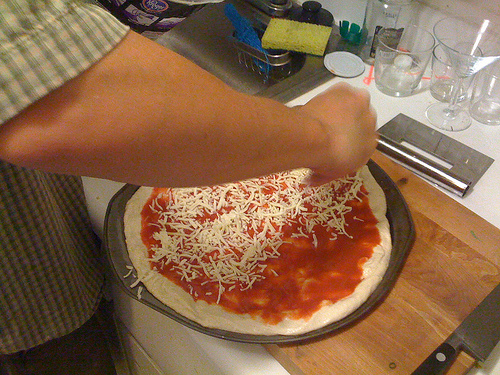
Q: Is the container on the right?
A: Yes, the container is on the right of the image.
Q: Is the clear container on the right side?
A: Yes, the container is on the right of the image.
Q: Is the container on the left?
A: No, the container is on the right of the image.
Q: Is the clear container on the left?
A: No, the container is on the right of the image.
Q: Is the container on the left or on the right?
A: The container is on the right of the image.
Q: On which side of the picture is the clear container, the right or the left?
A: The container is on the right of the image.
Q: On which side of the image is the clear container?
A: The container is on the right of the image.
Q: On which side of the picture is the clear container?
A: The container is on the right of the image.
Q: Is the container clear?
A: Yes, the container is clear.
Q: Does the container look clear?
A: Yes, the container is clear.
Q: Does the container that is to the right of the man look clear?
A: Yes, the container is clear.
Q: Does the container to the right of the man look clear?
A: Yes, the container is clear.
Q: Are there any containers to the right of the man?
A: Yes, there is a container to the right of the man.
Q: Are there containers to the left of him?
A: No, the container is to the right of the man.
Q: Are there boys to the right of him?
A: No, there is a container to the right of the man.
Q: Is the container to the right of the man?
A: Yes, the container is to the right of the man.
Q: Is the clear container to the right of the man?
A: Yes, the container is to the right of the man.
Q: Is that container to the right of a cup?
A: No, the container is to the right of the man.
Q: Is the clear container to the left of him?
A: No, the container is to the right of the man.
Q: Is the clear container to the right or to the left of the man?
A: The container is to the right of the man.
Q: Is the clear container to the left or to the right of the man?
A: The container is to the right of the man.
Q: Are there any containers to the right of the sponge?
A: Yes, there is a container to the right of the sponge.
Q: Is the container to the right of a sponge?
A: Yes, the container is to the right of a sponge.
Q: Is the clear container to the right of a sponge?
A: Yes, the container is to the right of a sponge.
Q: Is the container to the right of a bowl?
A: No, the container is to the right of a sponge.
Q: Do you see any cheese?
A: Yes, there is cheese.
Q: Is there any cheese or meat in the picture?
A: Yes, there is cheese.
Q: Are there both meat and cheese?
A: No, there is cheese but no meat.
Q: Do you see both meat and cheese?
A: No, there is cheese but no meat.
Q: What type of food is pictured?
A: The food is cheese.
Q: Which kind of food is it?
A: The food is cheese.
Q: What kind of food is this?
A: That is cheese.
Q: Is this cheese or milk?
A: This is cheese.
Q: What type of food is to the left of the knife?
A: The food is cheese.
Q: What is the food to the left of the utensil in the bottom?
A: The food is cheese.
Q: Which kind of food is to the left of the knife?
A: The food is cheese.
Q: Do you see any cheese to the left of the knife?
A: Yes, there is cheese to the left of the knife.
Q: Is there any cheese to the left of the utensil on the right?
A: Yes, there is cheese to the left of the knife.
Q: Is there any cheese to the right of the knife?
A: No, the cheese is to the left of the knife.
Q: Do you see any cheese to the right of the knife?
A: No, the cheese is to the left of the knife.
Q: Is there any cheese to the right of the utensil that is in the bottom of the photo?
A: No, the cheese is to the left of the knife.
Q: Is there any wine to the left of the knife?
A: No, there is cheese to the left of the knife.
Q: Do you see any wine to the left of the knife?
A: No, there is cheese to the left of the knife.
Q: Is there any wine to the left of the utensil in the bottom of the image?
A: No, there is cheese to the left of the knife.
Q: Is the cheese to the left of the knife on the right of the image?
A: Yes, the cheese is to the left of the knife.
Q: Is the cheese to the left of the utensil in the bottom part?
A: Yes, the cheese is to the left of the knife.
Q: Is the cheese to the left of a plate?
A: No, the cheese is to the left of the knife.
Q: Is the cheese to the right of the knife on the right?
A: No, the cheese is to the left of the knife.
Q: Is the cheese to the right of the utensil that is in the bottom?
A: No, the cheese is to the left of the knife.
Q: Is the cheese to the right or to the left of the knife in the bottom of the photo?
A: The cheese is to the left of the knife.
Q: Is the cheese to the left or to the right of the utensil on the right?
A: The cheese is to the left of the knife.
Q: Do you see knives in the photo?
A: Yes, there is a knife.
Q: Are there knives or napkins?
A: Yes, there is a knife.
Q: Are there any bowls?
A: No, there are no bowls.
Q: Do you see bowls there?
A: No, there are no bowls.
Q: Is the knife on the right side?
A: Yes, the knife is on the right of the image.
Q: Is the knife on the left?
A: No, the knife is on the right of the image.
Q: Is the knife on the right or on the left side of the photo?
A: The knife is on the right of the image.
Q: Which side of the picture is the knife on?
A: The knife is on the right of the image.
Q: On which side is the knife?
A: The knife is on the right of the image.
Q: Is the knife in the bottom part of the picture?
A: Yes, the knife is in the bottom of the image.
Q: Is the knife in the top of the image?
A: No, the knife is in the bottom of the image.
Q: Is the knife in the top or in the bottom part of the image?
A: The knife is in the bottom of the image.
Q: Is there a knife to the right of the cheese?
A: Yes, there is a knife to the right of the cheese.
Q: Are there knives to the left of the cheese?
A: No, the knife is to the right of the cheese.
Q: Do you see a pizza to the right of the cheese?
A: No, there is a knife to the right of the cheese.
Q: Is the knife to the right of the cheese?
A: Yes, the knife is to the right of the cheese.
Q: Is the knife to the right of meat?
A: No, the knife is to the right of the cheese.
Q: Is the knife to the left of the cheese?
A: No, the knife is to the right of the cheese.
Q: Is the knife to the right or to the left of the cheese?
A: The knife is to the right of the cheese.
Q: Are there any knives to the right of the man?
A: Yes, there is a knife to the right of the man.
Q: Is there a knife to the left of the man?
A: No, the knife is to the right of the man.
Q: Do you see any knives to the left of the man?
A: No, the knife is to the right of the man.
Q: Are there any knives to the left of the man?
A: No, the knife is to the right of the man.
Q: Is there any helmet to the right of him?
A: No, there is a knife to the right of the man.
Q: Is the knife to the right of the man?
A: Yes, the knife is to the right of the man.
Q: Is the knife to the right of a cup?
A: No, the knife is to the right of the man.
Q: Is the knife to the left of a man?
A: No, the knife is to the right of a man.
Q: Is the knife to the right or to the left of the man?
A: The knife is to the right of the man.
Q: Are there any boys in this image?
A: No, there are no boys.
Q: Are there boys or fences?
A: No, there are no boys or fences.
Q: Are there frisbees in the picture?
A: No, there are no frisbees.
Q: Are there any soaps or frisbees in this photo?
A: No, there are no frisbees or soaps.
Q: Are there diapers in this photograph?
A: No, there are no diapers.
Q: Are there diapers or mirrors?
A: No, there are no diapers or mirrors.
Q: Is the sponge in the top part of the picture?
A: Yes, the sponge is in the top of the image.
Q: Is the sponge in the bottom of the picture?
A: No, the sponge is in the top of the image.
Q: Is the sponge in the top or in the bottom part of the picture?
A: The sponge is in the top of the image.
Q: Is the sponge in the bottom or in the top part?
A: The sponge is in the top of the image.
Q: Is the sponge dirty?
A: Yes, the sponge is dirty.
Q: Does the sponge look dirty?
A: Yes, the sponge is dirty.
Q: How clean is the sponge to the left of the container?
A: The sponge is dirty.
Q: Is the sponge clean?
A: No, the sponge is dirty.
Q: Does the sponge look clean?
A: No, the sponge is dirty.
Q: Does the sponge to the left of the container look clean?
A: No, the sponge is dirty.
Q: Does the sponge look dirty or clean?
A: The sponge is dirty.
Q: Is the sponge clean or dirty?
A: The sponge is dirty.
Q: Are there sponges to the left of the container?
A: Yes, there is a sponge to the left of the container.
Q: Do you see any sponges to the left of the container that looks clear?
A: Yes, there is a sponge to the left of the container.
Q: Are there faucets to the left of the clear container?
A: No, there is a sponge to the left of the container.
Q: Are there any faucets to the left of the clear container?
A: No, there is a sponge to the left of the container.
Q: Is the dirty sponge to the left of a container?
A: Yes, the sponge is to the left of a container.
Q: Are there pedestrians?
A: No, there are no pedestrians.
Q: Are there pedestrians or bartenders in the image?
A: No, there are no pedestrians or bartenders.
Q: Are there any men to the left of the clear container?
A: Yes, there is a man to the left of the container.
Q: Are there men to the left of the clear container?
A: Yes, there is a man to the left of the container.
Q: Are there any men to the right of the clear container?
A: No, the man is to the left of the container.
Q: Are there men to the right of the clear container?
A: No, the man is to the left of the container.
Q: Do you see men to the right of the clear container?
A: No, the man is to the left of the container.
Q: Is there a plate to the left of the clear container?
A: No, there is a man to the left of the container.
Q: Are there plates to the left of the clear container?
A: No, there is a man to the left of the container.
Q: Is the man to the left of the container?
A: Yes, the man is to the left of the container.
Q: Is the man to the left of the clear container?
A: Yes, the man is to the left of the container.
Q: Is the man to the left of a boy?
A: No, the man is to the left of the container.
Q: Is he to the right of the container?
A: No, the man is to the left of the container.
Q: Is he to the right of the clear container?
A: No, the man is to the left of the container.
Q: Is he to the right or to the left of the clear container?
A: The man is to the left of the container.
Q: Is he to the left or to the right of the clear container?
A: The man is to the left of the container.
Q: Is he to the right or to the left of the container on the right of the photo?
A: The man is to the left of the container.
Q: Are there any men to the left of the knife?
A: Yes, there is a man to the left of the knife.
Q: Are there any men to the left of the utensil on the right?
A: Yes, there is a man to the left of the knife.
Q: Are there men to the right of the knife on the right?
A: No, the man is to the left of the knife.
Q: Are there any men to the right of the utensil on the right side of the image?
A: No, the man is to the left of the knife.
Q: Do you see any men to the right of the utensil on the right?
A: No, the man is to the left of the knife.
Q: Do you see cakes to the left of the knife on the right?
A: No, there is a man to the left of the knife.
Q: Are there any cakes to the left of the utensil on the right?
A: No, there is a man to the left of the knife.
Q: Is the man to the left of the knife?
A: Yes, the man is to the left of the knife.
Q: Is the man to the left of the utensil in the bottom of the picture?
A: Yes, the man is to the left of the knife.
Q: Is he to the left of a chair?
A: No, the man is to the left of the knife.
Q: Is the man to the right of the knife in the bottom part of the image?
A: No, the man is to the left of the knife.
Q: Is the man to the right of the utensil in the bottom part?
A: No, the man is to the left of the knife.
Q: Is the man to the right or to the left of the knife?
A: The man is to the left of the knife.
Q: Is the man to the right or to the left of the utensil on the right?
A: The man is to the left of the knife.